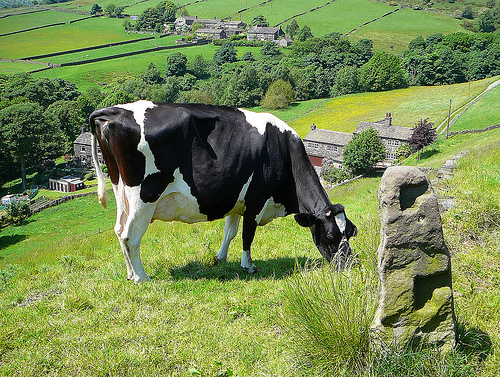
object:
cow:
[88, 99, 358, 285]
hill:
[0, 133, 500, 377]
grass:
[270, 232, 493, 377]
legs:
[114, 200, 265, 288]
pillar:
[368, 166, 458, 366]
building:
[303, 112, 416, 175]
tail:
[88, 111, 108, 210]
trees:
[0, 0, 500, 190]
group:
[161, 14, 292, 46]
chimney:
[384, 112, 392, 128]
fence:
[0, 58, 61, 69]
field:
[0, 0, 473, 94]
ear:
[294, 213, 323, 227]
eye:
[322, 232, 334, 243]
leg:
[120, 179, 159, 285]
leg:
[240, 202, 260, 275]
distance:
[2, 1, 499, 91]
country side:
[1, 2, 500, 377]